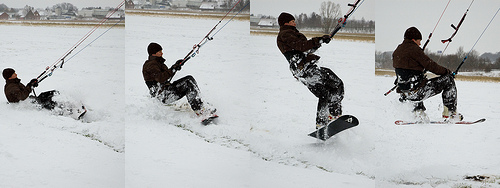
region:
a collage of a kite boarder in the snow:
[1, 1, 499, 186]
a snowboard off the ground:
[309, 112, 359, 144]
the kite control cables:
[171, 0, 249, 75]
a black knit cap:
[145, 40, 163, 55]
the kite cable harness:
[396, 68, 431, 90]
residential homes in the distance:
[1, 2, 124, 25]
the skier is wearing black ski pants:
[305, 67, 345, 120]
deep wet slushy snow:
[1, 117, 308, 187]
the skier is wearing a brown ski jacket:
[393, 40, 454, 78]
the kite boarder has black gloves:
[316, 33, 331, 45]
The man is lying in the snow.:
[1, 57, 101, 131]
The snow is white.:
[1, 26, 125, 186]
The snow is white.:
[128, 13, 248, 185]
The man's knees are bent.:
[128, 12, 247, 186]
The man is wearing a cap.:
[126, 11, 245, 186]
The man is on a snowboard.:
[263, 4, 373, 181]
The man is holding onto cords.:
[1, 4, 124, 186]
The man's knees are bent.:
[375, 3, 499, 184]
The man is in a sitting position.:
[376, 1, 498, 177]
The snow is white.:
[377, 1, 499, 185]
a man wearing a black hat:
[146, 37, 168, 64]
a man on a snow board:
[170, 75, 235, 145]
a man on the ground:
[3, 42, 121, 134]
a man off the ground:
[376, 19, 489, 145]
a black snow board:
[298, 110, 363, 165]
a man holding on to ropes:
[122, 4, 234, 115]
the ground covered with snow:
[7, 22, 66, 61]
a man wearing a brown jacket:
[141, 55, 167, 99]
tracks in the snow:
[158, 120, 283, 185]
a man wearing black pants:
[286, 51, 365, 136]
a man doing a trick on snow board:
[12, 8, 494, 148]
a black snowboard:
[296, 101, 363, 160]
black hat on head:
[270, 10, 320, 35]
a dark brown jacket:
[380, 33, 455, 78]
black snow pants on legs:
[156, 69, 228, 119]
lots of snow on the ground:
[7, 18, 477, 185]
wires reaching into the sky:
[166, 0, 264, 94]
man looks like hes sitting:
[382, 20, 482, 139]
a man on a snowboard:
[264, 13, 381, 160]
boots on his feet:
[393, 103, 480, 120]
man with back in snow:
[1, 42, 95, 123]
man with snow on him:
[1, 27, 113, 142]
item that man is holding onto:
[41, 23, 102, 80]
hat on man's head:
[142, 35, 172, 62]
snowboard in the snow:
[189, 94, 228, 139]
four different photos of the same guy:
[1, 5, 485, 161]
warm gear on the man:
[268, 17, 323, 76]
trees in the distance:
[298, 5, 338, 30]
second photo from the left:
[118, 3, 250, 158]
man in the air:
[376, 12, 493, 157]